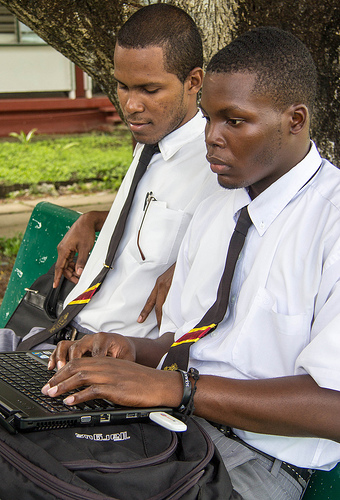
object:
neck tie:
[159, 205, 253, 371]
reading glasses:
[136, 194, 160, 265]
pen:
[141, 188, 156, 211]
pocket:
[128, 197, 182, 274]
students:
[0, 3, 227, 365]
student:
[38, 24, 339, 498]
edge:
[96, 388, 180, 404]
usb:
[148, 408, 186, 435]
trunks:
[0, 0, 339, 168]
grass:
[0, 130, 133, 202]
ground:
[0, 129, 131, 304]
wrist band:
[173, 365, 200, 419]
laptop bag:
[2, 416, 234, 497]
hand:
[41, 356, 181, 410]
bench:
[0, 201, 338, 497]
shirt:
[153, 138, 338, 473]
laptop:
[0, 348, 173, 437]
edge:
[181, 238, 244, 369]